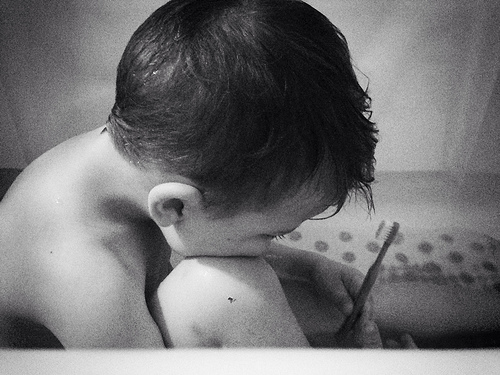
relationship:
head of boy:
[105, 5, 343, 240] [0, 0, 500, 350]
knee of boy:
[175, 261, 282, 335] [0, 0, 500, 350]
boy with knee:
[0, 0, 500, 350] [175, 261, 282, 335]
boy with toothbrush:
[0, 0, 500, 350] [332, 221, 395, 344]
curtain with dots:
[369, 14, 485, 278] [328, 223, 474, 284]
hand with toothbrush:
[315, 270, 369, 324] [345, 217, 395, 345]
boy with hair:
[8, 8, 405, 338] [109, 9, 371, 203]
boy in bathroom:
[8, 8, 405, 338] [5, 5, 482, 352]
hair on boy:
[120, 3, 388, 223] [8, 8, 405, 338]